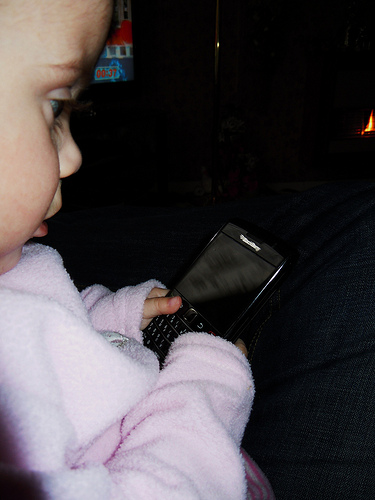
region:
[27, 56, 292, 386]
the baby is holding a phone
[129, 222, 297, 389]
blackberry being held by a child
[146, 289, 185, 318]
little girl's thumb on a phone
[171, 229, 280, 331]
blank blackberry screen reflecting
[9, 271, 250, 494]
pink fleece sweat shirt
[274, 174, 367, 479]
leg clad in denim pants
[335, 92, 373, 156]
fire burning in the fireplace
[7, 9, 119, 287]
baby face watching a phone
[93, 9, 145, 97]
television screen in the corner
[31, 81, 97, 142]
baby eye with long eyelashes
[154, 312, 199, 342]
keyboard on a blackberry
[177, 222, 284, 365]
shiny black blackberry cellphone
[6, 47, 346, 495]
SMALL BABY ON CELLPHONE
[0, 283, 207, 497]
FLUFFY PINK TOWEL FABRIC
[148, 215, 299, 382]
BLACKBERRY CELLPHONE BEING HELD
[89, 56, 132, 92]
TV SCREEN WITH 37 SECONDS ON IT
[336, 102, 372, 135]
ORANGE LIGHT OFF TO THE RIGHT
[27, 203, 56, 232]
LIPS OF SMALL CHILD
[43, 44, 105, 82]
THIN EYEBROW OF BABIES HEAD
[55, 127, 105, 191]
NOSE ON SMALL TODDLERS FACE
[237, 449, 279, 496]
PINK AND WHITE STRIPED BOTTOMS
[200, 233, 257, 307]
SCREEN OF BLACKBERRY PHONE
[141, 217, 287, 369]
phone is a blackberry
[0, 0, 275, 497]
baby wearing pink fuzzy clothes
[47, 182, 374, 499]
blue jeans under baby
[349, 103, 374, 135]
fireplace in back of shot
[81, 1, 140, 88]
Television behind person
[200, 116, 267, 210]
kid sitting in front of TV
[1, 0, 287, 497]
baby holding cell phone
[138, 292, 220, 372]
phone has several buttons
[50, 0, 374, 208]
room is darkly lit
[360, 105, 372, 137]
fireplace is lit with fire